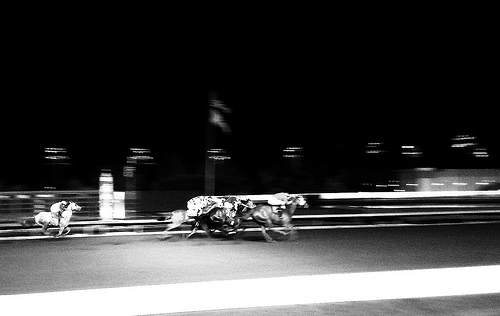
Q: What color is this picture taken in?
A: Black and White.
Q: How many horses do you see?
A: 4.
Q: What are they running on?
A: Dirt.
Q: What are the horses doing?
A: Racing.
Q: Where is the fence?
A: Behind the horses.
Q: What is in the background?
A: Darkness.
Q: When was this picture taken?
A: During the night.